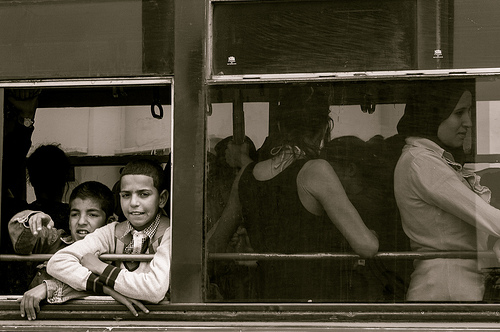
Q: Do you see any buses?
A: Yes, there is a bus.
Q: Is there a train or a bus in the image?
A: Yes, there is a bus.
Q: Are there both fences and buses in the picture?
A: No, there is a bus but no fences.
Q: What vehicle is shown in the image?
A: The vehicle is a bus.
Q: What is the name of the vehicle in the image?
A: The vehicle is a bus.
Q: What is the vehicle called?
A: The vehicle is a bus.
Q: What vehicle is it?
A: The vehicle is a bus.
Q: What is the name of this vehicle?
A: This is a bus.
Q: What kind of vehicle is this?
A: This is a bus.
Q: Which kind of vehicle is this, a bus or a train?
A: This is a bus.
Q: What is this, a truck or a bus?
A: This is a bus.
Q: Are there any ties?
A: Yes, there is a tie.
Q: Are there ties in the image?
A: Yes, there is a tie.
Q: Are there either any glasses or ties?
A: Yes, there is a tie.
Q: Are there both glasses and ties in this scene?
A: No, there is a tie but no glasses.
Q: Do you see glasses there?
A: No, there are no glasses.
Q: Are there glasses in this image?
A: No, there are no glasses.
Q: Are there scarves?
A: Yes, there is a scarf.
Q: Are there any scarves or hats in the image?
A: Yes, there is a scarf.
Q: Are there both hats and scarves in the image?
A: No, there is a scarf but no hats.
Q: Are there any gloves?
A: No, there are no gloves.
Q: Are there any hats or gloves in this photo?
A: No, there are no gloves or hats.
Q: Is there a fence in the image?
A: No, there are no fences.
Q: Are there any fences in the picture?
A: No, there are no fences.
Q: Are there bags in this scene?
A: No, there are no bags.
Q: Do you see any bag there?
A: No, there are no bags.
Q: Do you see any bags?
A: No, there are no bags.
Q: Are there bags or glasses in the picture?
A: No, there are no bags or glasses.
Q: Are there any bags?
A: No, there are no bags.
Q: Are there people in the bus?
A: Yes, there are people in the bus.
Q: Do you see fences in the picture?
A: No, there are no fences.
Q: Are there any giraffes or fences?
A: No, there are no fences or giraffes.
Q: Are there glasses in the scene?
A: No, there are no glasses.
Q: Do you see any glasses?
A: No, there are no glasses.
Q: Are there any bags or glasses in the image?
A: No, there are no glasses or bags.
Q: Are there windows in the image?
A: Yes, there is a window.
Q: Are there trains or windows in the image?
A: Yes, there is a window.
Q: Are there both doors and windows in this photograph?
A: No, there is a window but no doors.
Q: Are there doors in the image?
A: No, there are no doors.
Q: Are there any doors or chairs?
A: No, there are no doors or chairs.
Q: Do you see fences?
A: No, there are no fences.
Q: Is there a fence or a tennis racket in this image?
A: No, there are no fences or rackets.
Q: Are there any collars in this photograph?
A: Yes, there is a collar.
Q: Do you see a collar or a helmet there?
A: Yes, there is a collar.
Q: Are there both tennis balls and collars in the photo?
A: No, there is a collar but no tennis balls.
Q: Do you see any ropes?
A: No, there are no ropes.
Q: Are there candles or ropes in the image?
A: No, there are no ropes or candles.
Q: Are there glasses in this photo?
A: No, there are no glasses.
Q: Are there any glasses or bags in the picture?
A: No, there are no glasses or bags.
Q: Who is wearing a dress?
A: The lady is wearing a dress.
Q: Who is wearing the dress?
A: The lady is wearing a dress.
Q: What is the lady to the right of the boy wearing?
A: The lady is wearing a dress.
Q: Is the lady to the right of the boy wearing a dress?
A: Yes, the lady is wearing a dress.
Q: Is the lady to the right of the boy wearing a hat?
A: No, the lady is wearing a dress.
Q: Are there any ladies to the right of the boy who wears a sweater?
A: Yes, there is a lady to the right of the boy.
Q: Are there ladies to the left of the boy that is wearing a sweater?
A: No, the lady is to the right of the boy.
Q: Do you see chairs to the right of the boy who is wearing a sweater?
A: No, there is a lady to the right of the boy.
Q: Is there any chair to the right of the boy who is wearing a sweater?
A: No, there is a lady to the right of the boy.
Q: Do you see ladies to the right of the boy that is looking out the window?
A: Yes, there is a lady to the right of the boy.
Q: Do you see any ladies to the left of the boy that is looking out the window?
A: No, the lady is to the right of the boy.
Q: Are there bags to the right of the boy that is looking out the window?
A: No, there is a lady to the right of the boy.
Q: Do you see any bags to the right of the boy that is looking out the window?
A: No, there is a lady to the right of the boy.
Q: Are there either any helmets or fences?
A: No, there are no fences or helmets.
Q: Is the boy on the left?
A: Yes, the boy is on the left of the image.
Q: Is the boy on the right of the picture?
A: No, the boy is on the left of the image.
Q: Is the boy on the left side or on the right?
A: The boy is on the left of the image.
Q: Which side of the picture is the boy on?
A: The boy is on the left of the image.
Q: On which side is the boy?
A: The boy is on the left of the image.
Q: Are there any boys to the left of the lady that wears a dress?
A: Yes, there is a boy to the left of the lady.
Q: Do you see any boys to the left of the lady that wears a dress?
A: Yes, there is a boy to the left of the lady.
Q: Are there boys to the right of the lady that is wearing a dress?
A: No, the boy is to the left of the lady.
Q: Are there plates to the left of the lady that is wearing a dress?
A: No, there is a boy to the left of the lady.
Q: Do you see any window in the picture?
A: Yes, there is a window.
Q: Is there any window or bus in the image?
A: Yes, there is a window.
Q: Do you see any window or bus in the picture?
A: Yes, there is a window.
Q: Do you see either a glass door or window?
A: Yes, there is a glass window.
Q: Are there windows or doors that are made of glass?
A: Yes, the window is made of glass.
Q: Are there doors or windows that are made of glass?
A: Yes, the window is made of glass.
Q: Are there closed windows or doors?
A: Yes, there is a closed window.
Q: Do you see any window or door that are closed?
A: Yes, the window is closed.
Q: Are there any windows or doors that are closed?
A: Yes, the window is closed.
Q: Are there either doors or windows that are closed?
A: Yes, the window is closed.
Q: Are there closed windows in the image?
A: Yes, there is a closed window.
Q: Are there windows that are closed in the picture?
A: Yes, there is a closed window.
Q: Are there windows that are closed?
A: Yes, there is a window that is closed.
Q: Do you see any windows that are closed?
A: Yes, there is a window that is closed.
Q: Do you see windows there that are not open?
A: Yes, there is an closed window.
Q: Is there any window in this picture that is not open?
A: Yes, there is an closed window.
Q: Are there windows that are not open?
A: Yes, there is an closed window.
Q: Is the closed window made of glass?
A: Yes, the window is made of glass.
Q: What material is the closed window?
A: The window is made of glass.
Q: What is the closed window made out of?
A: The window is made of glass.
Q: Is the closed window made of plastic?
A: No, the window is made of glass.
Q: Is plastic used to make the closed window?
A: No, the window is made of glass.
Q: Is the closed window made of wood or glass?
A: The window is made of glass.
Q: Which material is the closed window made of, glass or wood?
A: The window is made of glass.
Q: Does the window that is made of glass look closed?
A: Yes, the window is closed.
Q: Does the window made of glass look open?
A: No, the window is closed.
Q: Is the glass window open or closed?
A: The window is closed.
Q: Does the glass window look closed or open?
A: The window is closed.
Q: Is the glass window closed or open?
A: The window is closed.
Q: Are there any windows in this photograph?
A: Yes, there is a window.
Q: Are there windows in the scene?
A: Yes, there is a window.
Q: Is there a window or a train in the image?
A: Yes, there is a window.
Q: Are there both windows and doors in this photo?
A: No, there is a window but no doors.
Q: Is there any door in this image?
A: No, there are no doors.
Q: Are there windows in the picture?
A: Yes, there is a window.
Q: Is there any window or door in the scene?
A: Yes, there is a window.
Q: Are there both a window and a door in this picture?
A: No, there is a window but no doors.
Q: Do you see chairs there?
A: No, there are no chairs.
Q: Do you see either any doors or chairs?
A: No, there are no chairs or doors.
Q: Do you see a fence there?
A: No, there are no fences.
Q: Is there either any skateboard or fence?
A: No, there are no fences or skateboards.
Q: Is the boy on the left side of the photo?
A: Yes, the boy is on the left of the image.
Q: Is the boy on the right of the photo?
A: No, the boy is on the left of the image.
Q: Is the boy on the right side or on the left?
A: The boy is on the left of the image.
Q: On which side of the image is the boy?
A: The boy is on the left of the image.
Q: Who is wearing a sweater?
A: The boy is wearing a sweater.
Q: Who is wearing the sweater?
A: The boy is wearing a sweater.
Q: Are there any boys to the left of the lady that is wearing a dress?
A: Yes, there is a boy to the left of the lady.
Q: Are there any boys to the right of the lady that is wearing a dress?
A: No, the boy is to the left of the lady.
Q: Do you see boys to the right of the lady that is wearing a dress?
A: No, the boy is to the left of the lady.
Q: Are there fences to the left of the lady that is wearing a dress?
A: No, there is a boy to the left of the lady.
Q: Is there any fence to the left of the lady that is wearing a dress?
A: No, there is a boy to the left of the lady.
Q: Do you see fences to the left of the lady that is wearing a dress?
A: No, there is a boy to the left of the lady.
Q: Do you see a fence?
A: No, there are no fences.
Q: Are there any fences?
A: No, there are no fences.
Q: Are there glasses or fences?
A: No, there are no fences or glasses.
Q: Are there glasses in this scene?
A: No, there are no glasses.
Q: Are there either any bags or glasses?
A: No, there are no glasses or bags.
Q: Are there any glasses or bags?
A: No, there are no glasses or bags.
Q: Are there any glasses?
A: No, there are no glasses.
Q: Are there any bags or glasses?
A: No, there are no glasses or bags.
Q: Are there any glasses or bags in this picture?
A: No, there are no glasses or bags.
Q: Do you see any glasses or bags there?
A: No, there are no glasses or bags.